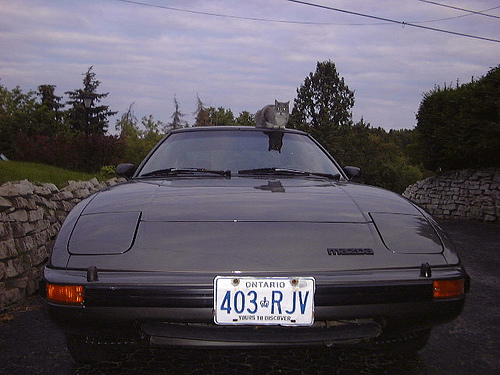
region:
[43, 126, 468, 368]
an expensive looking black car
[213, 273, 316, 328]
a Canadian license plate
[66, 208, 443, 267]
headlights of vehicle are concealed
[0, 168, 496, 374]
rustic-looking stone walls on both sides of a lane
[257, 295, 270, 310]
small crown on license plate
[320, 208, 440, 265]
car brand near its right headlight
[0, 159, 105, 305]
grass covered area behind wall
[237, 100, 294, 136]
a grey cat perched on top of car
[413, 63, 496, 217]
green hedge above wall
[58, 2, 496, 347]
power lines above car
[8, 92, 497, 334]
a black sports car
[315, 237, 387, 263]
the Mazda logo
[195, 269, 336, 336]
a white license plate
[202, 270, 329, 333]
a license plate with blue letters and numbers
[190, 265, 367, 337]
an Ontario license plate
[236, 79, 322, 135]
a grey cat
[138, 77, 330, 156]
the cat is on the roof of the car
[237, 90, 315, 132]
grey and white cat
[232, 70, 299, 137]
grey and white cat on a car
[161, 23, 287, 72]
The sky is cloudy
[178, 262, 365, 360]
Ontario plates are on the car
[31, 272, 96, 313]
The lights are off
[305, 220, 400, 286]
The car is a mazda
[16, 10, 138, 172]
The trees are tall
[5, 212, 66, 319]
The wall is made of stone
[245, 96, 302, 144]
The cat is on the car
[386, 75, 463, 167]
The bushes are green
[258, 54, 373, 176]
The tree leaves are green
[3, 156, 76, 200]
The grass is cut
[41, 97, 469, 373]
Cat laying on the roof of a black Mazda car.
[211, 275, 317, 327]
Blue and white Ontario, Canada license plate on bumper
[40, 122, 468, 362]
Front end of black Mazda car from the front view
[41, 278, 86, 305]
Auto turn signal light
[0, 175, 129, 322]
Rock wall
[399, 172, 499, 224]
Stone wall going around bend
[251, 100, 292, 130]
Gray and white cat with glowing eyes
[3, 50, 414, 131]
Conifer trees outline againt dusky sky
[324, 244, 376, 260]
Mazda car logo on hood of car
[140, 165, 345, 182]
Auto windshield wipers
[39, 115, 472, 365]
front of parked black corvette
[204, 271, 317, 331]
blue and white licence plate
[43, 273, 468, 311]
two orange headlights on front of black corvette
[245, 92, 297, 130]
grey cat on top of black corvette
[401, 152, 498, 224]
short grey stone wall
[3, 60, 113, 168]
line of green trees bordering grass field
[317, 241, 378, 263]
car brand name on front of car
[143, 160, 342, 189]
two windshield wipers on front of black car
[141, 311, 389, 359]
grill on front of car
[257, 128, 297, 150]
reflection of cat in windshield